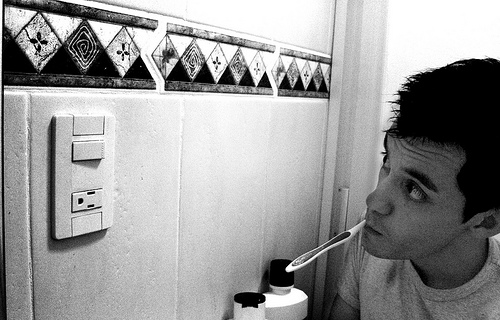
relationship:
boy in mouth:
[328, 58, 500, 320] [356, 214, 388, 240]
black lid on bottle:
[268, 258, 293, 287] [262, 259, 306, 320]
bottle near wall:
[221, 289, 318, 317] [2, 0, 336, 316]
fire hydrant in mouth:
[285, 219, 366, 273] [360, 214, 381, 243]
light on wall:
[51, 113, 114, 241] [36, 112, 120, 241]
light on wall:
[49, 109, 115, 241] [2, 0, 336, 316]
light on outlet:
[51, 113, 114, 241] [44, 169, 145, 216]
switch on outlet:
[69, 114, 108, 140] [44, 169, 145, 216]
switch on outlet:
[67, 140, 107, 166] [44, 169, 145, 216]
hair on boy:
[383, 58, 498, 223] [328, 56, 498, 318]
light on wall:
[51, 113, 114, 241] [21, 4, 305, 315]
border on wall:
[6, 3, 347, 98] [2, 0, 336, 316]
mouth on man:
[359, 216, 388, 241] [319, 54, 497, 315]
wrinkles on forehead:
[400, 146, 445, 166] [373, 132, 477, 174]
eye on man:
[382, 148, 392, 168] [319, 54, 497, 315]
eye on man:
[395, 173, 432, 207] [319, 54, 497, 315]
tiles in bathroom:
[7, 4, 337, 104] [4, 7, 498, 318]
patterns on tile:
[140, 52, 322, 97] [3, 10, 331, 110]